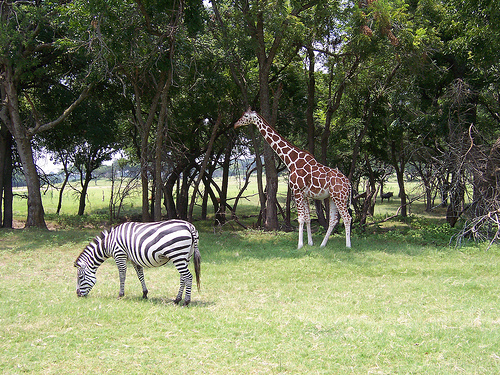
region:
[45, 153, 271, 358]
the zebra has stripes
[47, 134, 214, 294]
the zebra has stripes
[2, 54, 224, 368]
the zebra has stripes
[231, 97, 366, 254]
THE GIRAFFE IS TALL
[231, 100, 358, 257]
THE GIRAFFE IS BIG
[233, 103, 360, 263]
THE GIRAFFE HAS SPOTS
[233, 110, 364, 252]
THE GIRAFFE HAS A LONG NECK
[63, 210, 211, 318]
THE ZEBRA IS BIG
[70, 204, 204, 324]
THE ZEBRA HAS STRIPES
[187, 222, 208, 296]
THE ZEBRA HAS A BUSHY TAIL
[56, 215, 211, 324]
THE ZEBRA EATS GRASS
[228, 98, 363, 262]
THE GIRAFFE EATS LEAVES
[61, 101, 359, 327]
THE ANIMALS ARE CLOSE TOGETHER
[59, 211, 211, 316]
zebra standing in grass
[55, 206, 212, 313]
zebra grazing on grass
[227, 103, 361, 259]
giraffe standing in grass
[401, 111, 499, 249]
pile of brush in front of trees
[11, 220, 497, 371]
grassy area in front of trees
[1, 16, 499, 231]
rows of trees in grass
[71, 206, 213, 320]
zebra is black and white stripes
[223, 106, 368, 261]
giraffe is brown and white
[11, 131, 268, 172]
patches of sky through the clouds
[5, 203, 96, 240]
patch of dirt around trees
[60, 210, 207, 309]
this is a zebra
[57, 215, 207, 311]
the zebra is feeding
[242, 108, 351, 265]
this is s giraffe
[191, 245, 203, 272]
this is the tail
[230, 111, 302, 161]
the giraffe has long neck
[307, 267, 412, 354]
the grass are green in color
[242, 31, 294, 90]
the tree is tall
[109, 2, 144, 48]
the leaves are green in color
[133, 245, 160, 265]
the belly is fat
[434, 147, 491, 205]
the branch is dry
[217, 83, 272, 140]
this is a giraffe head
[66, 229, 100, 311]
this is a head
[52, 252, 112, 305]
black and white head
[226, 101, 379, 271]
this is a giraffe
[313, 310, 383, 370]
this is green grass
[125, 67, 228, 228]
this is a tree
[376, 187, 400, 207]
this is a pig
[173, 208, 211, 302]
this is a tail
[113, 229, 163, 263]
these are black stripes